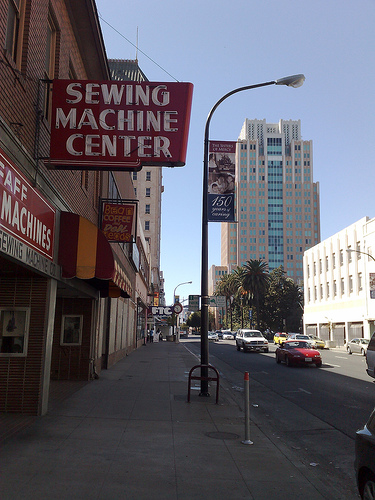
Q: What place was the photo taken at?
A: It was taken at the sidewalk.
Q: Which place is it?
A: It is a sidewalk.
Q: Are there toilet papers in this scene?
A: No, there are no toilet papers.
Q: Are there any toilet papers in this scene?
A: No, there are no toilet papers.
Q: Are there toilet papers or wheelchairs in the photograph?
A: No, there are no toilet papers or wheelchairs.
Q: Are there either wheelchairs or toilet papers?
A: No, there are no toilet papers or wheelchairs.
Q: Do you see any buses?
A: No, there are no buses.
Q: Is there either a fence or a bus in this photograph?
A: No, there are no buses or fences.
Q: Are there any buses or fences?
A: No, there are no buses or fences.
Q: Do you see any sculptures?
A: No, there are no sculptures.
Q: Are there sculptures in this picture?
A: No, there are no sculptures.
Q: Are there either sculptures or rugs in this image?
A: No, there are no sculptures or rugs.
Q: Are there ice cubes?
A: No, there are no ice cubes.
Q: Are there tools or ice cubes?
A: No, there are no ice cubes or tools.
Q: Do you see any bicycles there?
A: No, there are no bicycles.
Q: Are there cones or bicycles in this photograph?
A: No, there are no bicycles or cones.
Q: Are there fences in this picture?
A: No, there are no fences.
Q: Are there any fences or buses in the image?
A: No, there are no fences or buses.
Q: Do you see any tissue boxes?
A: No, there are no tissue boxes.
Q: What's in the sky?
A: The clouds are in the sky.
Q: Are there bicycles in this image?
A: No, there are no bicycles.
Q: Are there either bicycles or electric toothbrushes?
A: No, there are no bicycles or electric toothbrushes.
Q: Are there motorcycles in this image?
A: No, there are no motorcycles.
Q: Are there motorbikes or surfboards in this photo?
A: No, there are no motorbikes or surfboards.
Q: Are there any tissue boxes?
A: No, there are no tissue boxes.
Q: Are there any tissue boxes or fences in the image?
A: No, there are no tissue boxes or fences.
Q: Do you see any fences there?
A: No, there are no fences.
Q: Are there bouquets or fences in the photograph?
A: No, there are no fences or bouquets.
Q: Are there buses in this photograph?
A: No, there are no buses.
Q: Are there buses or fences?
A: No, there are no buses or fences.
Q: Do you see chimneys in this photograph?
A: No, there are no chimneys.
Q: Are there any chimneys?
A: No, there are no chimneys.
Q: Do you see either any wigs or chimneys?
A: No, there are no chimneys or wigs.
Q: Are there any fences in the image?
A: No, there are no fences.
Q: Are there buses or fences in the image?
A: No, there are no fences or buses.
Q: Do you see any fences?
A: No, there are no fences.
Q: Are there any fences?
A: No, there are no fences.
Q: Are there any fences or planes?
A: No, there are no fences or planes.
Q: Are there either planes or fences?
A: No, there are no fences or planes.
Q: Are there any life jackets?
A: No, there are no life jackets.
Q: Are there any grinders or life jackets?
A: No, there are no life jackets or grinders.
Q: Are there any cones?
A: No, there are no cones.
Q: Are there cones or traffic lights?
A: No, there are no cones or traffic lights.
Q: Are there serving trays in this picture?
A: No, there are no serving trays.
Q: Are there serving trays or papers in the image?
A: No, there are no serving trays or papers.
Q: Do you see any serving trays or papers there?
A: No, there are no serving trays or papers.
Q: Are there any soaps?
A: No, there are no soaps.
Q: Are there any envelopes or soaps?
A: No, there are no soaps or envelopes.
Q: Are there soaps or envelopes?
A: No, there are no soaps or envelopes.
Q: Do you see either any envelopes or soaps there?
A: No, there are no soaps or envelopes.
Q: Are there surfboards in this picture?
A: No, there are no surfboards.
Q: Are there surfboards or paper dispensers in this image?
A: No, there are no surfboards or paper dispensers.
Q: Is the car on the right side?
A: Yes, the car is on the right of the image.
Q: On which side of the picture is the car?
A: The car is on the right of the image.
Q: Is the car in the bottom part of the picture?
A: Yes, the car is in the bottom of the image.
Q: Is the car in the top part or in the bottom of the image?
A: The car is in the bottom of the image.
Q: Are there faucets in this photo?
A: No, there are no faucets.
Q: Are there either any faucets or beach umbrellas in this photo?
A: No, there are no faucets or beach umbrellas.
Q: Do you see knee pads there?
A: No, there are no knee pads.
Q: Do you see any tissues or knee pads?
A: No, there are no knee pads or tissues.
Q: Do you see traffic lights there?
A: No, there are no traffic lights.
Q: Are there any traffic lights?
A: No, there are no traffic lights.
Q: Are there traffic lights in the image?
A: No, there are no traffic lights.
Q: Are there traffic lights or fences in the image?
A: No, there are no traffic lights or fences.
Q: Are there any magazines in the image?
A: No, there are no magazines.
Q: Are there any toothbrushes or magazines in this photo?
A: No, there are no magazines or toothbrushes.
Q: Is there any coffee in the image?
A: Yes, there is coffee.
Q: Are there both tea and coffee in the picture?
A: No, there is coffee but no tea.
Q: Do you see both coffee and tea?
A: No, there is coffee but no tea.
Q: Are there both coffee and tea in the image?
A: No, there is coffee but no tea.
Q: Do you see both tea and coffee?
A: No, there is coffee but no tea.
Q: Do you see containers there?
A: No, there are no containers.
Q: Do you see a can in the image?
A: No, there are no cans.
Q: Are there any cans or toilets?
A: No, there are no cans or toilets.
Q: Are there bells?
A: No, there are no bells.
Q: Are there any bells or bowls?
A: No, there are no bells or bowls.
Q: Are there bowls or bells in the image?
A: No, there are no bells or bowls.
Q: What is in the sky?
A: The clouds are in the sky.